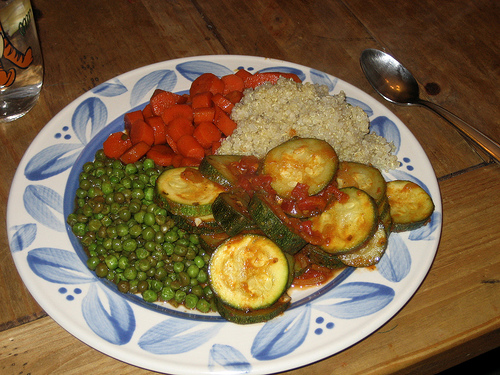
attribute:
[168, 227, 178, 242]
pea — green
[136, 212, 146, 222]
pea — green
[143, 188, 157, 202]
pea — green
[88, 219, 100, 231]
pea — green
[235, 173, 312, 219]
sauce — Cut up tomato 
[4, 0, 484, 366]
table — wooden, Edge